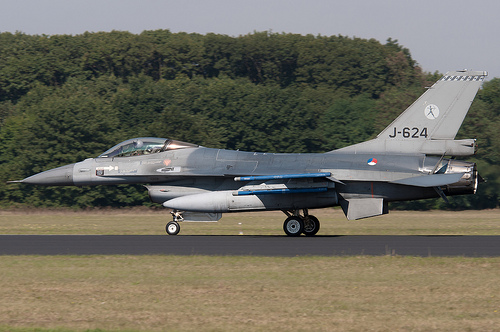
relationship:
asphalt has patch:
[0, 233, 497, 254] [330, 235, 351, 250]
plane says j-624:
[6, 69, 484, 241] [385, 122, 432, 147]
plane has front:
[6, 69, 484, 241] [6, 159, 74, 198]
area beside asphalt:
[0, 253, 496, 329] [0, 235, 500, 255]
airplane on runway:
[7, 68, 488, 235] [2, 231, 498, 252]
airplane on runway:
[7, 68, 488, 235] [2, 227, 498, 253]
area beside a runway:
[0, 208, 481, 233] [1, 232, 484, 254]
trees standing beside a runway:
[1, 29, 484, 211] [0, 233, 484, 259]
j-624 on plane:
[389, 127, 428, 139] [6, 69, 484, 241]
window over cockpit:
[94, 135, 199, 159] [81, 132, 208, 170]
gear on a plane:
[164, 204, 324, 238] [6, 69, 484, 241]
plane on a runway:
[6, 69, 484, 241] [1, 231, 483, 258]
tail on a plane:
[373, 67, 484, 141] [6, 69, 484, 241]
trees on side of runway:
[1, 29, 484, 211] [0, 230, 484, 256]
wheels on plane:
[277, 206, 323, 239] [6, 69, 484, 241]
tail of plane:
[373, 67, 484, 141] [6, 69, 484, 241]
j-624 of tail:
[389, 127, 428, 139] [373, 67, 484, 141]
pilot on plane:
[127, 137, 147, 157] [6, 69, 484, 241]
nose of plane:
[4, 159, 78, 189] [6, 69, 484, 241]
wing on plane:
[231, 167, 338, 197] [6, 69, 484, 241]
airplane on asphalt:
[7, 70, 484, 236] [0, 235, 500, 255]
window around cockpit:
[97, 137, 198, 158] [94, 132, 197, 160]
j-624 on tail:
[389, 127, 428, 139] [373, 67, 484, 141]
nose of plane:
[6, 163, 75, 186] [6, 69, 484, 241]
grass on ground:
[0, 252, 482, 330] [0, 203, 483, 330]